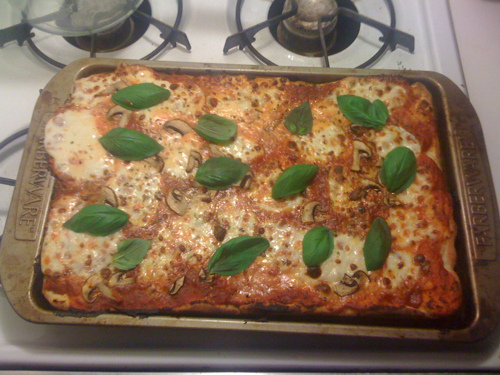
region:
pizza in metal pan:
[3, 54, 498, 344]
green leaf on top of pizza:
[59, 188, 133, 238]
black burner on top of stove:
[219, 0, 420, 68]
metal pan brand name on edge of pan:
[446, 104, 498, 274]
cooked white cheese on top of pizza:
[37, 74, 462, 325]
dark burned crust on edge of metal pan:
[53, 308, 100, 322]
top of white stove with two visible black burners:
[0, 0, 495, 372]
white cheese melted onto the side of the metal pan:
[31, 101, 99, 200]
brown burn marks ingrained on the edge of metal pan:
[2, 251, 36, 298]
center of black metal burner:
[273, 0, 350, 50]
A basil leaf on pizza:
[200, 226, 276, 288]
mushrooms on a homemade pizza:
[152, 185, 227, 243]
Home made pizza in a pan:
[29, 58, 471, 327]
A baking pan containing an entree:
[6, 43, 498, 352]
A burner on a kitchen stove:
[220, 0, 404, 69]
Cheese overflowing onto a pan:
[23, 97, 103, 196]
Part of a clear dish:
[1, 0, 152, 45]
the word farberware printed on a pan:
[432, 105, 498, 277]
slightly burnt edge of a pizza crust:
[43, 296, 458, 327]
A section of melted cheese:
[157, 217, 209, 257]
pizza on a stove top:
[4, 6, 488, 358]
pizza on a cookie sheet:
[1, 56, 490, 350]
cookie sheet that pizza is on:
[2, 55, 498, 355]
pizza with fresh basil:
[32, 58, 472, 327]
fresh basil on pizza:
[67, 73, 420, 290]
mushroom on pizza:
[349, 139, 369, 171]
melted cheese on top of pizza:
[41, 108, 118, 183]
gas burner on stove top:
[227, 3, 417, 66]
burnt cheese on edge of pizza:
[56, 297, 453, 327]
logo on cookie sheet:
[11, 118, 63, 242]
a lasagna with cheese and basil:
[47, 67, 461, 312]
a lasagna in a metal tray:
[2, 55, 493, 339]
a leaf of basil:
[113, 79, 168, 111]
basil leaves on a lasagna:
[63, 81, 420, 277]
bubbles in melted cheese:
[50, 113, 70, 147]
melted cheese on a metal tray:
[40, 105, 62, 171]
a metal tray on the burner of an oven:
[3, 55, 497, 347]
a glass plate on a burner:
[13, 0, 145, 36]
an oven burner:
[220, 0, 416, 70]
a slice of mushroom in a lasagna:
[351, 139, 371, 174]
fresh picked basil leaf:
[107, 80, 170, 110]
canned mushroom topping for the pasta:
[76, 80, 419, 305]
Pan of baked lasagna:
[0, 55, 495, 340]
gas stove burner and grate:
[220, 0, 415, 66]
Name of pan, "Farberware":
[456, 126, 491, 246]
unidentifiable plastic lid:
[5, 0, 150, 35]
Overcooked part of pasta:
[240, 297, 305, 312]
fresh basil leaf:
[360, 210, 392, 272]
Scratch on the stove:
[455, 71, 465, 86]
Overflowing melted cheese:
[38, 101, 111, 187]